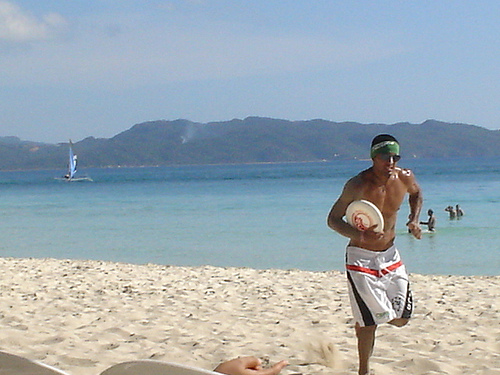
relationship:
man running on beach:
[324, 133, 426, 374] [24, 253, 498, 373]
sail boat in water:
[48, 128, 131, 216] [122, 157, 265, 258]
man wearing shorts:
[324, 133, 426, 374] [331, 242, 424, 329]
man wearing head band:
[324, 133, 426, 374] [359, 137, 419, 167]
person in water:
[441, 202, 469, 224] [93, 175, 359, 307]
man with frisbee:
[307, 112, 463, 368] [338, 187, 396, 242]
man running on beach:
[307, 112, 463, 368] [48, 248, 365, 372]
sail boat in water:
[51, 138, 98, 183] [2, 155, 498, 290]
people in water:
[421, 200, 466, 233] [0, 156, 499, 274]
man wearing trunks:
[324, 133, 426, 374] [329, 241, 440, 315]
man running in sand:
[324, 133, 426, 374] [1, 255, 497, 372]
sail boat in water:
[51, 138, 98, 183] [0, 156, 499, 274]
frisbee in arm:
[343, 197, 386, 235] [327, 173, 383, 241]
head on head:
[370, 133, 402, 175] [370, 133, 402, 175]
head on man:
[370, 133, 402, 175] [324, 133, 426, 374]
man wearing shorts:
[324, 133, 426, 374] [342, 241, 419, 328]